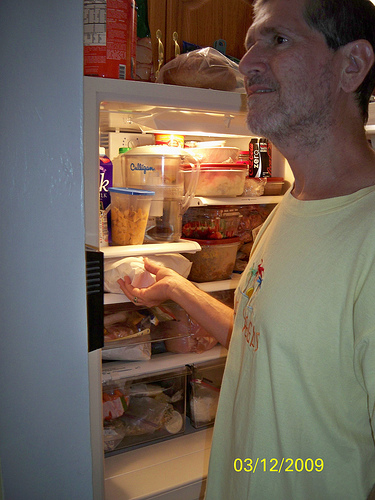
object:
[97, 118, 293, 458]
food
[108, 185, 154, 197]
lid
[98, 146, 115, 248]
soy milk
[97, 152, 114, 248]
carton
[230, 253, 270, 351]
design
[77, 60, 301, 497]
fridge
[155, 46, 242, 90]
bread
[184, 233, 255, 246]
lid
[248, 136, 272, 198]
coke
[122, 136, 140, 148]
thermostat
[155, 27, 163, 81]
handle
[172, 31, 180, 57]
handle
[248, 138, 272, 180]
soda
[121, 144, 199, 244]
container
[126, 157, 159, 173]
brand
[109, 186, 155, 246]
container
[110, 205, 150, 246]
left-overs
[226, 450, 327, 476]
date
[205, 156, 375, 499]
shirt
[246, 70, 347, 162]
hair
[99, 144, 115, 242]
steps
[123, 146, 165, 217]
milk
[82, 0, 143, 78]
container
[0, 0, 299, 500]
cabinet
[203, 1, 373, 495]
man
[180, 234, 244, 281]
container